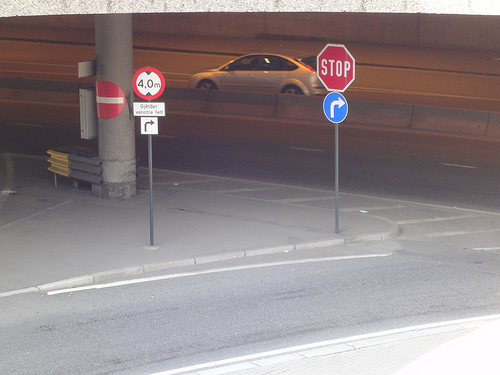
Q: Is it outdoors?
A: Yes, it is outdoors.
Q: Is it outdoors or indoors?
A: It is outdoors.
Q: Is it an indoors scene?
A: No, it is outdoors.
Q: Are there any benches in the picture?
A: No, there are no benches.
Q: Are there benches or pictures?
A: No, there are no benches or pictures.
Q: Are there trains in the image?
A: No, there are no trains.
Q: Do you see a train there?
A: No, there are no trains.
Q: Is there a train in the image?
A: No, there are no trains.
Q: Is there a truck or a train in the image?
A: No, there are no trains or trucks.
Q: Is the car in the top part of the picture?
A: Yes, the car is in the top of the image.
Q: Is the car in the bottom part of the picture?
A: No, the car is in the top of the image.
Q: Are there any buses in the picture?
A: No, there are no buses.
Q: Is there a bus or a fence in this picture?
A: No, there are no buses or fences.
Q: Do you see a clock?
A: No, there are no clocks.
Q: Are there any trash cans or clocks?
A: No, there are no clocks or trash cans.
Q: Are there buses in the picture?
A: No, there are no buses.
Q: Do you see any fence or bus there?
A: No, there are no buses or fences.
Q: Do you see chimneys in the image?
A: No, there are no chimneys.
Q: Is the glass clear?
A: Yes, the glass is clear.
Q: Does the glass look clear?
A: Yes, the glass is clear.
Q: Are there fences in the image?
A: No, there are no fences.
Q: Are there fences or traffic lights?
A: No, there are no fences or traffic lights.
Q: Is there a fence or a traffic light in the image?
A: No, there are no fences or traffic lights.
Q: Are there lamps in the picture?
A: No, there are no lamps.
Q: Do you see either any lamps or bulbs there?
A: No, there are no lamps or bulbs.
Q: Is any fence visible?
A: No, there are no fences.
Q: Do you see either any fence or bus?
A: No, there are no fences or buses.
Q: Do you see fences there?
A: No, there are no fences.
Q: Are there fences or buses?
A: No, there are no fences or buses.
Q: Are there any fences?
A: No, there are no fences.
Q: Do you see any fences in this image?
A: No, there are no fences.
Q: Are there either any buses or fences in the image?
A: No, there are no fences or buses.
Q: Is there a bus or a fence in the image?
A: No, there are no fences or buses.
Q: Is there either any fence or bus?
A: No, there are no fences or buses.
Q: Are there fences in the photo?
A: No, there are no fences.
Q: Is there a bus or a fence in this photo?
A: No, there are no fences or buses.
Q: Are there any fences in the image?
A: No, there are no fences.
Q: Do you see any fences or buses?
A: No, there are no fences or buses.